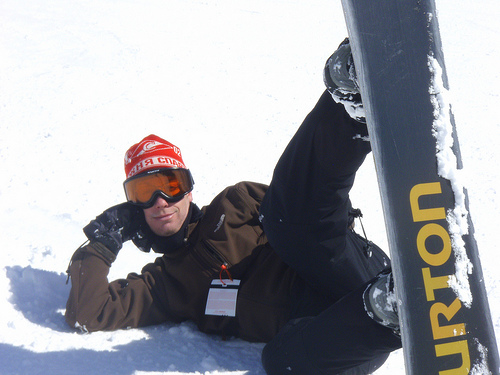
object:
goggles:
[122, 167, 194, 209]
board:
[338, 0, 499, 375]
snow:
[26, 25, 87, 154]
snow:
[74, 32, 256, 82]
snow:
[3, 5, 267, 135]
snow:
[0, 156, 60, 364]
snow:
[12, 13, 254, 94]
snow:
[0, 44, 66, 375]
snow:
[372, 205, 383, 235]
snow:
[4, 335, 240, 370]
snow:
[0, 0, 500, 375]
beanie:
[123, 134, 187, 179]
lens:
[125, 170, 192, 204]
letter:
[410, 182, 447, 223]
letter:
[416, 223, 452, 266]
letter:
[421, 267, 455, 301]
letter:
[429, 298, 467, 340]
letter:
[432, 339, 471, 375]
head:
[123, 134, 195, 237]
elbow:
[64, 300, 111, 334]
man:
[62, 36, 402, 375]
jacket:
[64, 181, 296, 343]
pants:
[259, 87, 402, 375]